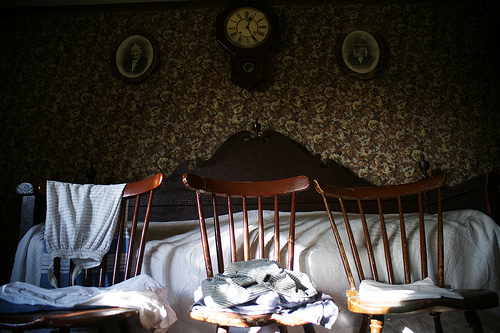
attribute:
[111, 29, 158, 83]
portrait — black, white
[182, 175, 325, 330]
chair — wooden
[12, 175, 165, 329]
chair — wooden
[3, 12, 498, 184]
wall paper — floral, gold, brown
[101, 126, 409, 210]
head board — wooden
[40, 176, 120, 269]
garment — white striped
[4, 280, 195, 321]
clothing — white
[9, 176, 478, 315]
chairs — wooden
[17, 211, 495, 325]
bedspread — white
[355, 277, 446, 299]
towel — white